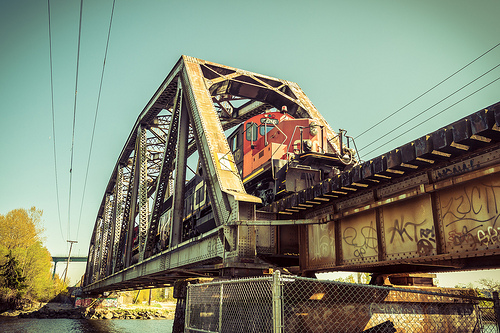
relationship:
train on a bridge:
[110, 104, 365, 254] [52, 63, 497, 332]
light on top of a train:
[279, 104, 290, 113] [123, 102, 357, 249]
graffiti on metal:
[386, 212, 434, 254] [292, 177, 499, 269]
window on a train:
[240, 121, 265, 144] [126, 100, 358, 220]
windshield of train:
[242, 121, 257, 141] [102, 110, 352, 268]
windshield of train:
[260, 123, 275, 134] [102, 110, 352, 268]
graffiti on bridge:
[370, 190, 495, 253] [31, 67, 498, 286]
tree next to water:
[0, 204, 68, 319] [2, 299, 177, 331]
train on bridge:
[92, 102, 357, 257] [69, 55, 479, 331]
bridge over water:
[69, 55, 479, 331] [0, 314, 173, 330]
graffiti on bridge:
[334, 178, 499, 260] [74, 52, 499, 295]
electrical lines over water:
[47, 0, 114, 256] [9, 317, 176, 332]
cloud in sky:
[19, 41, 134, 158] [3, 0, 423, 284]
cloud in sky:
[19, 121, 103, 212] [197, 14, 444, 112]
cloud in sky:
[40, 184, 100, 285] [0, 1, 497, 285]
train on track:
[92, 102, 357, 257] [259, 102, 496, 212]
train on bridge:
[71, 103, 361, 293] [74, 52, 499, 295]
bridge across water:
[74, 52, 499, 295] [3, 319, 173, 331]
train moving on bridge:
[88, 105, 356, 286] [119, 173, 495, 265]